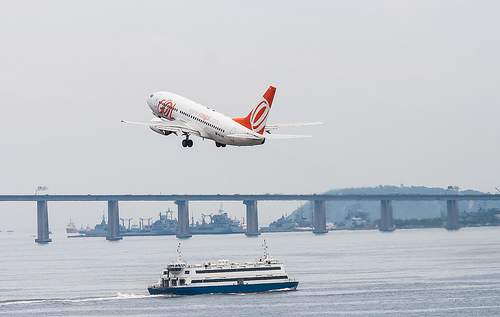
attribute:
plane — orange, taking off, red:
[133, 79, 323, 150]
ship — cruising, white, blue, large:
[149, 242, 301, 298]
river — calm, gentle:
[9, 214, 500, 308]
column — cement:
[34, 196, 53, 242]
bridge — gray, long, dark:
[10, 179, 500, 238]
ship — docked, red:
[60, 214, 85, 239]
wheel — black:
[180, 136, 196, 153]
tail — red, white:
[233, 84, 279, 142]